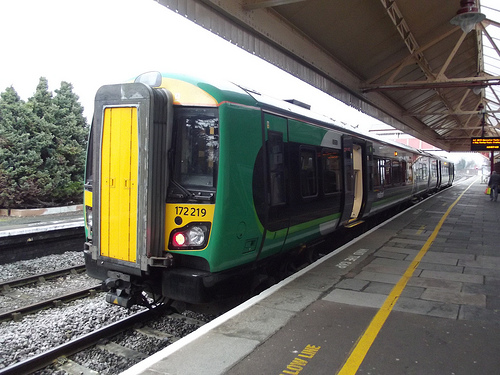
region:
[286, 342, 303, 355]
small white spot on platform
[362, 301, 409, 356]
solid yellow line on platform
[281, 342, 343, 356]
yellow words on the platform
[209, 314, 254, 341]
white edge of platform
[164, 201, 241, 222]
black words on the train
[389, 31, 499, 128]
overhead beams at the train station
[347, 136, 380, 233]
long white door on the train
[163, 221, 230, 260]
bright light on the train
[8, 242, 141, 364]
long train silver tracks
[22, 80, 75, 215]
large green trees in the background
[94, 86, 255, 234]
this is a train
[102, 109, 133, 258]
this is the door of the train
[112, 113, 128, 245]
the door is yellow in color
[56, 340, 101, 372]
this is the railway line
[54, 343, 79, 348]
this is a metal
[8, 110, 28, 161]
this is a tree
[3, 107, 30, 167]
the tree has green leaves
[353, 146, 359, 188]
the door of the train is opened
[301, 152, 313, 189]
this is a window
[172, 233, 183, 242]
the light is on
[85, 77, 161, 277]
gray and yellow door on train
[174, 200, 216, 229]
black numbers on yellow train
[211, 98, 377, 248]
green and white cars on train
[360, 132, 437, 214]
green and white cars on train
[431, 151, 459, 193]
green and white cars on train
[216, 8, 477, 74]
brown and gray overhang at train station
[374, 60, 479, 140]
brown and gray overhang at train station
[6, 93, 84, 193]
green trees by train station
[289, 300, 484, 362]
yellow stripe on gray train platform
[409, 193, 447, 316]
yellow stripe on gray train platform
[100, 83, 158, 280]
Train back door closed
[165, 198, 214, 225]
The number 172219 in black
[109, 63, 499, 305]
A train station with train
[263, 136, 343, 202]
Windows on side of train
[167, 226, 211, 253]
Train headlights at front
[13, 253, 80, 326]
Train tracks without train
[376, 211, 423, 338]
Yellow line on side walk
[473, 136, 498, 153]
LED sign used for information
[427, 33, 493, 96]
Steal raptors used for support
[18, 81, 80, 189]
Green pine tree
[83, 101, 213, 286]
the train is yellow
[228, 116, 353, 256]
the side is green in color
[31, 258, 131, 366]
there is gravel on the tracks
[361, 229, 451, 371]
the line is yellow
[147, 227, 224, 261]
the light is on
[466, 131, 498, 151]
the writing is illminated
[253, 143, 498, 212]
the train has stopped at a trainstation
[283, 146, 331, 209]
the windows are square in shape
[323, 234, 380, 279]
there is white writing on the pavement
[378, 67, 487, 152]
the roofing has metallic frame